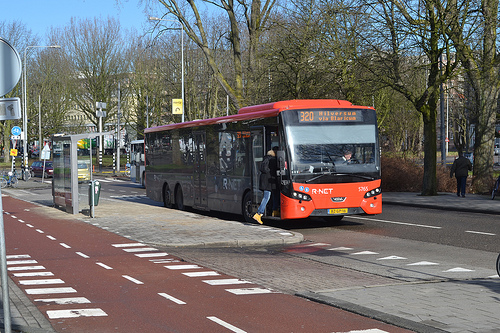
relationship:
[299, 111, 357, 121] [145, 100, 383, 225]
digital sign on bus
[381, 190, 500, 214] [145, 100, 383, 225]
sidewalk near bus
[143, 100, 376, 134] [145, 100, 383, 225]
roof on bus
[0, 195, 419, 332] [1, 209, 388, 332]
surface has lines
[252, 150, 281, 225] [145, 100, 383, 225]
person boarding bus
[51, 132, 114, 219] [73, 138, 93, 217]
bus shelter has a glass wall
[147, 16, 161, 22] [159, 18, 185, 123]
street light on pole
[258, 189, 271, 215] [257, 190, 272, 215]
leg in jeans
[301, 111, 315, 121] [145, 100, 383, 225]
number on bus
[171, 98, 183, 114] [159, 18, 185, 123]
traffic sign on pole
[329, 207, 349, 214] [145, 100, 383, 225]
license plate on bus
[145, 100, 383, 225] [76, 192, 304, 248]
bus stopped at curb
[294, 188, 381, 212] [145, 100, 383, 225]
headlights are on bus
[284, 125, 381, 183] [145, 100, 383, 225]
windshield on bus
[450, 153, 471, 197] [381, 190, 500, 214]
person on sidewalk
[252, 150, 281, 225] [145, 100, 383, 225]
person getting on bus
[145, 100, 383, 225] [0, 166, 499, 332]
bus on city street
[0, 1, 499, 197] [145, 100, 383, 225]
trees are behind bus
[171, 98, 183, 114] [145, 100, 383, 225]
traffic sign behind bus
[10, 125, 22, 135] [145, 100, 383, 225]
traffic sign behind bus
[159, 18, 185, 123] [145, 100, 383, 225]
pole behind bus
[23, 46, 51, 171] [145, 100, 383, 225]
pole behind bus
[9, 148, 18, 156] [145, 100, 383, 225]
sign behind bus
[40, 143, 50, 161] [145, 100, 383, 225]
sign behind bus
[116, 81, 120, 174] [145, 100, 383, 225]
pole behind bus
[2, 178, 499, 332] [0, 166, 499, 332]
lines on city street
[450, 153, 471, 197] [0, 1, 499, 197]
person walking towards trees